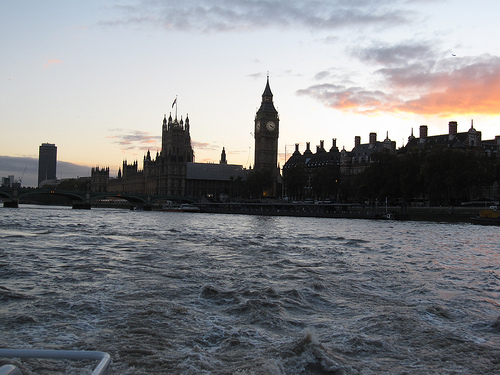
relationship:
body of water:
[1, 203, 499, 373] [0, 202, 499, 374]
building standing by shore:
[38, 142, 60, 186] [0, 186, 499, 222]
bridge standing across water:
[0, 181, 203, 214] [0, 202, 499, 374]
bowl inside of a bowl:
[481, 207, 499, 222] [477, 207, 499, 222]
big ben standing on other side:
[252, 75, 281, 201] [1, 0, 499, 205]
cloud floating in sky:
[116, 127, 215, 157] [1, 1, 498, 188]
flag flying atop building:
[171, 94, 181, 120] [90, 69, 281, 201]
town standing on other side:
[0, 66, 499, 208] [1, 0, 499, 205]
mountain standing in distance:
[1, 154, 119, 197] [1, 137, 499, 186]